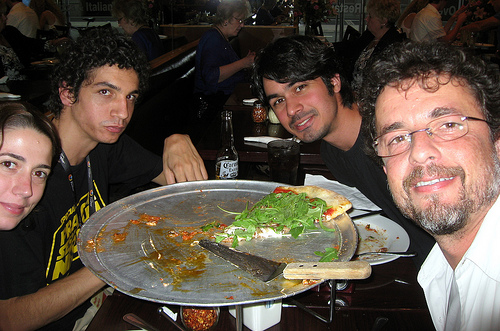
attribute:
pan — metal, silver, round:
[88, 174, 342, 307]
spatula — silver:
[203, 248, 374, 291]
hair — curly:
[348, 55, 492, 169]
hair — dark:
[261, 24, 347, 94]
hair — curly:
[57, 35, 153, 101]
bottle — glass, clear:
[198, 101, 247, 186]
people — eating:
[7, 13, 499, 49]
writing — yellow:
[40, 188, 102, 286]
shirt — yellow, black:
[1, 114, 149, 283]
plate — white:
[347, 212, 407, 269]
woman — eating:
[194, 4, 267, 105]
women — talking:
[186, 5, 407, 96]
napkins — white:
[312, 176, 383, 222]